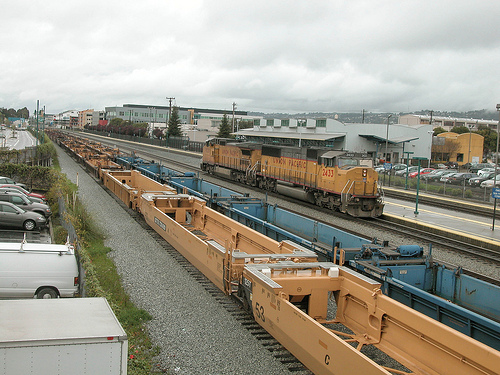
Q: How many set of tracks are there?
A: 4.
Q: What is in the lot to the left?
A: Vehicles.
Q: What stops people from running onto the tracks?
A: Fence.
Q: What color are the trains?
A: Yellow and blue.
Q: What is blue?
A: Train car.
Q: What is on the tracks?
A: A train.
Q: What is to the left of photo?
A: Cars parked.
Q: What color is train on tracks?
A: Yellow.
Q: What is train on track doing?
A: Moving.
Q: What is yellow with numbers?
A: Yellow train on track.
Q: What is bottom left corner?
A: White trailer.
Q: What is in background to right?
A: Building with cars.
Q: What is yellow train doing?
A: Moving on rail tracks.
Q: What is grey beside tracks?
A: Gravel.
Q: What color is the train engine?
A: Black and yellow.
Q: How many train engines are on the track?
A: Two.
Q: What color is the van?
A: White.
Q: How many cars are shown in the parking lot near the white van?
A: Five.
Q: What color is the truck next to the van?
A: White.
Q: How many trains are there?
A: One.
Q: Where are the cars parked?
A: In the parking lot.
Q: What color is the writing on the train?
A: Red.